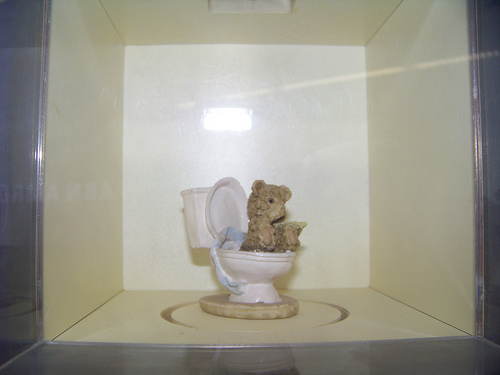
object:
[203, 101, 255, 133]
light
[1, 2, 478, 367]
wall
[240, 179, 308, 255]
bear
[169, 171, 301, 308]
toilet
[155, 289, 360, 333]
circle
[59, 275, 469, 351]
ground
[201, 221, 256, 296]
ribbon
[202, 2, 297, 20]
vent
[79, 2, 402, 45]
ceiling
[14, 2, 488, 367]
frame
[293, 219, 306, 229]
edge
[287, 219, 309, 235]
cup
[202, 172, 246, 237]
lid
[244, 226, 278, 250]
leg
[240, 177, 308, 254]
doll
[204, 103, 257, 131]
reflection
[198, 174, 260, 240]
up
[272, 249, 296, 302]
front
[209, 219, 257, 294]
blanket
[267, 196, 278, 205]
eye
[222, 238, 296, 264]
bowl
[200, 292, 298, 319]
platform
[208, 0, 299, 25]
square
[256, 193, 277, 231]
brown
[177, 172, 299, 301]
miniature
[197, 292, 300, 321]
base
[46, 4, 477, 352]
glass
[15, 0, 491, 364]
display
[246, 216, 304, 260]
body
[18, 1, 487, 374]
case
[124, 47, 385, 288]
interior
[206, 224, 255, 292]
blue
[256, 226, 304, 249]
pads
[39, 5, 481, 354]
scene